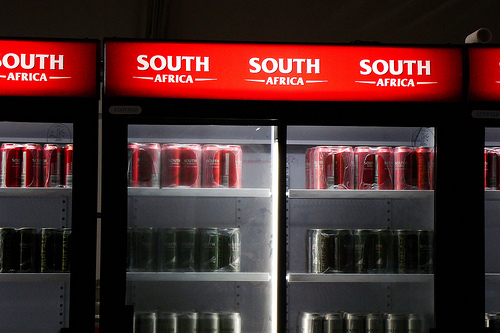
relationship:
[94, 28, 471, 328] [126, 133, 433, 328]
fridge full of drinks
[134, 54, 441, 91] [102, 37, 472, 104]
lettering on red background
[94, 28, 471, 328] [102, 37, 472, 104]
fridge has red top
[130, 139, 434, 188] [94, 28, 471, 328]
cans in fridge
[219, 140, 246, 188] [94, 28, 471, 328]
can in a cooler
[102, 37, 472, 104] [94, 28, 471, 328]
sign on fridge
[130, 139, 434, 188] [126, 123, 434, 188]
cans wrapped in plastic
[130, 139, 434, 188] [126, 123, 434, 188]
cans on top shelf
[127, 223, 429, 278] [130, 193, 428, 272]
cans are on middle shelf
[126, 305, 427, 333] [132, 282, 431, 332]
cans are on bottom shelf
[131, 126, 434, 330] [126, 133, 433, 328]
rear surface color white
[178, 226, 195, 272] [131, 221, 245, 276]
can has wrapper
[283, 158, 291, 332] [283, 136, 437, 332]
holes on wall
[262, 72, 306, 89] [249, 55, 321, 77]
word africa under south